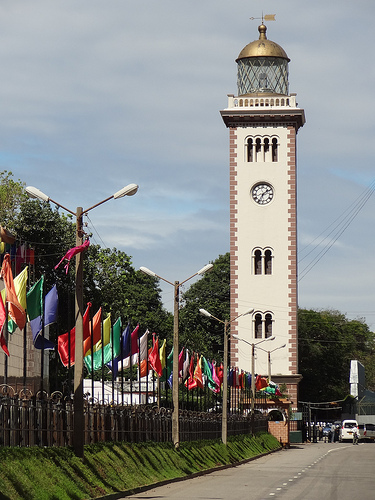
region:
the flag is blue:
[46, 296, 54, 311]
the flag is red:
[62, 339, 70, 351]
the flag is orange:
[92, 319, 98, 336]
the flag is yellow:
[104, 321, 108, 337]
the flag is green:
[113, 327, 119, 342]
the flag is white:
[139, 339, 147, 352]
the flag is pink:
[132, 331, 140, 345]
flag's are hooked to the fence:
[109, 312, 154, 340]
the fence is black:
[93, 374, 148, 394]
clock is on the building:
[248, 177, 275, 205]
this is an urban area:
[8, 19, 331, 482]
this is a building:
[192, 99, 328, 377]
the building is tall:
[208, 34, 329, 437]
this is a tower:
[189, 57, 282, 295]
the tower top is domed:
[216, 34, 331, 93]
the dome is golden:
[219, 38, 303, 70]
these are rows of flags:
[29, 262, 243, 411]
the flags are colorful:
[18, 267, 195, 381]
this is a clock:
[233, 160, 299, 202]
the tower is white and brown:
[197, 167, 351, 333]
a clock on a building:
[242, 177, 263, 198]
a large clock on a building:
[252, 174, 286, 223]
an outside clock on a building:
[251, 177, 285, 219]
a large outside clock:
[241, 168, 293, 275]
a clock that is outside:
[279, 199, 313, 253]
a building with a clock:
[243, 168, 337, 283]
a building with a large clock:
[243, 173, 281, 216]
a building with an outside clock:
[244, 162, 292, 227]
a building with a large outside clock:
[238, 176, 278, 216]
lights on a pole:
[132, 246, 286, 389]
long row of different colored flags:
[2, 265, 278, 424]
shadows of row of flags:
[0, 434, 263, 488]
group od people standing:
[315, 424, 341, 442]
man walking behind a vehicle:
[347, 418, 366, 444]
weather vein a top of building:
[236, 11, 293, 109]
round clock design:
[230, 174, 294, 214]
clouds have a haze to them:
[143, 177, 218, 260]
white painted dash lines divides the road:
[253, 445, 347, 493]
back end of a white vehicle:
[338, 417, 355, 440]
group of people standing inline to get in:
[306, 422, 340, 446]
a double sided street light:
[27, 185, 138, 458]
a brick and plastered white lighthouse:
[222, 13, 301, 448]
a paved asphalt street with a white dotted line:
[122, 442, 374, 497]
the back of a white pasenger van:
[337, 421, 357, 441]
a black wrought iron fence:
[1, 385, 270, 444]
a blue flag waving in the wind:
[31, 287, 58, 351]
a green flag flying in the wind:
[85, 318, 120, 370]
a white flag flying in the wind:
[110, 332, 149, 370]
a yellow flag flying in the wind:
[0, 268, 28, 314]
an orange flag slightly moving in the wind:
[1, 254, 24, 331]